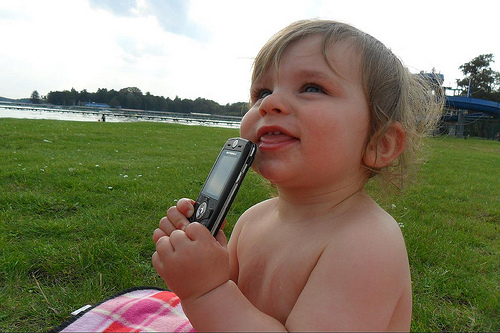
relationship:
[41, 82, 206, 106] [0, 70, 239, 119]
trees in distance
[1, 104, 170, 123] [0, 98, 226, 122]
water in front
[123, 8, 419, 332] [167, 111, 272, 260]
child holds phone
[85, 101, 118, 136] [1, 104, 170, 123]
person near water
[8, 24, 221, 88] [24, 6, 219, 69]
sky has clouds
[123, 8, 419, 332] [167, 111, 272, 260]
toddler holding phone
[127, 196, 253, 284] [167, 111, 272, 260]
hands holding cellphone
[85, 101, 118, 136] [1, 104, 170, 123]
person by water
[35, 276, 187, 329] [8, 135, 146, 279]
blanket in grass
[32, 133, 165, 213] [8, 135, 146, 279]
flowers in grass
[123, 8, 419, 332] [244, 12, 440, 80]
baby has hair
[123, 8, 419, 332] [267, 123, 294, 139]
baby has teeth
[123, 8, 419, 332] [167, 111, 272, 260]
baby holding phone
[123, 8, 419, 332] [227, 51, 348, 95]
baby has eyes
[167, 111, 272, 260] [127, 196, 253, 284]
phone in hands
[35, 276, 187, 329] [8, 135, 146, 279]
blanket on grass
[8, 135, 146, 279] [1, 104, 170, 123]
grass near water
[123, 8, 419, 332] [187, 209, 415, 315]
baby wearing no shirt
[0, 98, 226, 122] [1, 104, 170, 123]
pier in water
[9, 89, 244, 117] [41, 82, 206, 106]
line of trees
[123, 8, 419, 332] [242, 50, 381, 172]
baby looking up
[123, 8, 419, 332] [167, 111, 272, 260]
baby holding cellphone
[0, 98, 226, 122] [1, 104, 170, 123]
pier across water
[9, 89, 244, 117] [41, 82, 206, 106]
row of trees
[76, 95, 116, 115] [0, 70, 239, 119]
house in distance